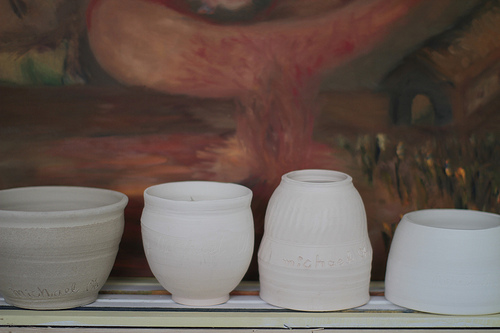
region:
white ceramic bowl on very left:
[0, 184, 127, 310]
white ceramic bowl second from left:
[139, 179, 254, 306]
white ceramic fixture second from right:
[256, 168, 373, 313]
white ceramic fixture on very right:
[382, 207, 497, 316]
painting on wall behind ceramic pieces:
[0, 0, 498, 280]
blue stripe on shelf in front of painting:
[0, 303, 417, 312]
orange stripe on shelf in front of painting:
[97, 289, 384, 296]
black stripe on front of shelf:
[1, 323, 498, 330]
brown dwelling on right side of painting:
[315, 0, 498, 165]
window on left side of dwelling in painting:
[460, 60, 499, 117]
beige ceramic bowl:
[0, 180, 128, 316]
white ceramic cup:
[135, 172, 257, 327]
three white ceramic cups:
[134, 168, 499, 320]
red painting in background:
[1, 0, 498, 185]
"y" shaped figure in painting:
[83, 6, 427, 166]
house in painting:
[384, 22, 495, 130]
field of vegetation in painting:
[347, 126, 494, 211]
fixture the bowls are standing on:
[5, 290, 480, 327]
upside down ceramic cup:
[256, 166, 389, 320]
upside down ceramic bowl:
[382, 203, 498, 320]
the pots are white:
[43, 162, 457, 332]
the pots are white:
[162, 159, 284, 325]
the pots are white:
[277, 169, 483, 331]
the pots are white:
[197, 156, 372, 326]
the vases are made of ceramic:
[25, 157, 492, 319]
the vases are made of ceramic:
[14, 162, 164, 330]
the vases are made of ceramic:
[188, 177, 308, 325]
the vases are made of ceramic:
[300, 164, 482, 316]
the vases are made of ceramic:
[242, 144, 402, 316]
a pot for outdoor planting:
[0, 180, 131, 313]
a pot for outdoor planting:
[135, 176, 258, 308]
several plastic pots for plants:
[257, 163, 374, 314]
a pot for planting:
[379, 196, 499, 321]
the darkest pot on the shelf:
[0, 183, 129, 328]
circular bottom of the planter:
[279, 165, 356, 190]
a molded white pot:
[135, 183, 259, 308]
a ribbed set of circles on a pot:
[0, 218, 127, 262]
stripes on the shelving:
[84, 269, 171, 329]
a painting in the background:
[3, 19, 498, 197]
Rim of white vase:
[142, 179, 254, 206]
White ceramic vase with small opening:
[255, 168, 373, 308]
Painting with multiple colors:
[249, 66, 426, 171]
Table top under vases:
[155, 302, 392, 327]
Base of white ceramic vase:
[257, 289, 375, 311]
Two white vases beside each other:
[139, 167, 376, 312]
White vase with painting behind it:
[381, 161, 498, 316]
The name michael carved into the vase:
[275, 244, 360, 273]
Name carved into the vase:
[7, 278, 104, 303]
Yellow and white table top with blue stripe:
[112, 288, 163, 318]